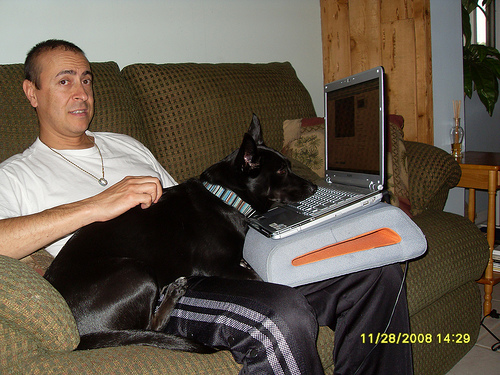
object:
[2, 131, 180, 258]
t-shirt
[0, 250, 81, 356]
pillow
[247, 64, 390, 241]
laptop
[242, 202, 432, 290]
stand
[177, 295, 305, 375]
stripes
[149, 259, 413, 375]
pants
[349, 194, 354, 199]
key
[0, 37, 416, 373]
man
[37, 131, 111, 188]
necklace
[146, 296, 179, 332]
leg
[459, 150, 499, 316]
table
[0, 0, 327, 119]
wall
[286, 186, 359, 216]
keyboard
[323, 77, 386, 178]
screen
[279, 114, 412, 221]
pillow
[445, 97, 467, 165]
item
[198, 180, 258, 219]
collar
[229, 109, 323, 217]
head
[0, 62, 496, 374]
couch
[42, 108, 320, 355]
dog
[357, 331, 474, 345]
stamp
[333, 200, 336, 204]
key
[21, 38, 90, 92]
hair